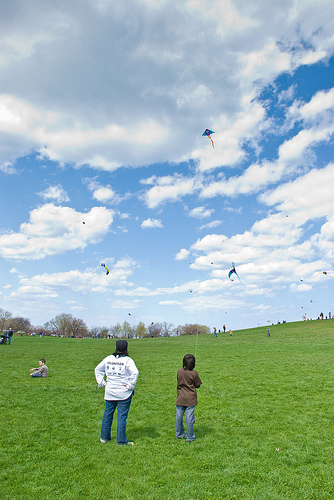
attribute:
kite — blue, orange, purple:
[201, 125, 217, 149]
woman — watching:
[92, 336, 141, 447]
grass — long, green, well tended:
[0, 317, 333, 500]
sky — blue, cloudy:
[0, 1, 332, 338]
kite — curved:
[225, 265, 244, 282]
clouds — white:
[7, 1, 333, 311]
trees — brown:
[0, 309, 209, 340]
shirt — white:
[93, 355, 140, 403]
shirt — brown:
[176, 367, 202, 410]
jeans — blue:
[102, 389, 134, 448]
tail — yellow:
[207, 133, 216, 147]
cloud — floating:
[0, 202, 115, 264]